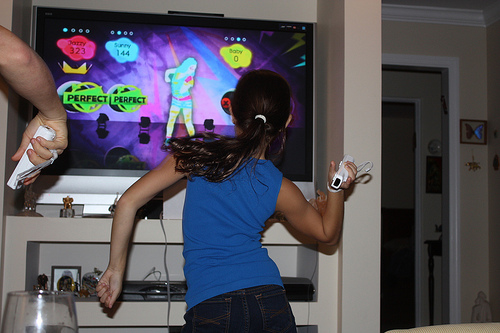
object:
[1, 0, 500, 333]
house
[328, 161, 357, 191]
hand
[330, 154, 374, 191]
control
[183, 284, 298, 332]
jeans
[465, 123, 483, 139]
butterfly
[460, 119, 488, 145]
frame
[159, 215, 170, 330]
wire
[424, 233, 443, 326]
console table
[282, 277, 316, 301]
console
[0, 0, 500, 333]
room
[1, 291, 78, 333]
glass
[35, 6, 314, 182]
game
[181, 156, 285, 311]
shirt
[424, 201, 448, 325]
table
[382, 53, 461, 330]
door way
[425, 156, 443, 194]
ground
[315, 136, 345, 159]
ground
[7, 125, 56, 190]
controller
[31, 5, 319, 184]
tv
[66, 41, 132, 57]
scores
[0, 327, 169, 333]
table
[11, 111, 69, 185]
hand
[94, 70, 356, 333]
girl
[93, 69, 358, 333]
recreation